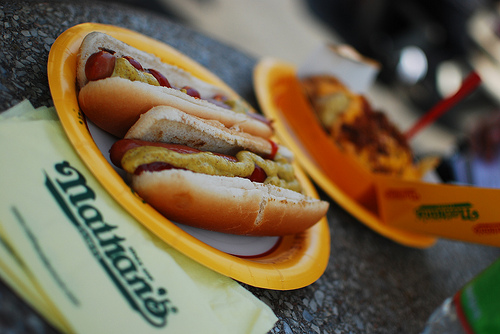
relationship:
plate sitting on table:
[41, 19, 334, 294] [5, 6, 488, 328]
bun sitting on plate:
[119, 102, 329, 239] [41, 19, 334, 294]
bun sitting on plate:
[75, 30, 276, 151] [41, 19, 334, 294]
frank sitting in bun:
[106, 135, 296, 184] [119, 102, 329, 239]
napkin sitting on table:
[4, 94, 279, 328] [5, 6, 488, 328]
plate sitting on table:
[252, 56, 437, 248] [5, 6, 488, 328]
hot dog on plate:
[108, 100, 328, 236] [41, 19, 334, 294]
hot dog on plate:
[72, 23, 275, 141] [41, 19, 334, 294]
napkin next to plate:
[4, 94, 279, 334] [41, 19, 334, 294]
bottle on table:
[419, 252, 496, 329] [5, 6, 488, 328]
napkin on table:
[4, 94, 279, 334] [5, 6, 488, 328]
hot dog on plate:
[109, 137, 304, 194] [48, 292, 329, 319]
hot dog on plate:
[83, 50, 277, 133] [48, 292, 329, 319]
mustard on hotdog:
[122, 150, 305, 189] [107, 150, 299, 190]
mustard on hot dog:
[102, 50, 165, 88] [83, 50, 277, 133]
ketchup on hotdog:
[105, 141, 304, 192] [115, 137, 303, 190]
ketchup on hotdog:
[111, 51, 204, 97] [78, 44, 276, 128]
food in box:
[294, 68, 414, 178] [270, 62, 499, 247]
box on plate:
[270, 62, 499, 247] [252, 56, 437, 248]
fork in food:
[393, 65, 485, 146] [293, 71, 444, 182]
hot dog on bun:
[109, 137, 304, 194] [119, 102, 329, 239]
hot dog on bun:
[83, 50, 277, 133] [72, 29, 278, 142]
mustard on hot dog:
[122, 150, 305, 189] [108, 156, 298, 179]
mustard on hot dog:
[109, 57, 160, 89] [83, 51, 277, 127]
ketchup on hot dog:
[262, 140, 281, 166] [108, 156, 298, 179]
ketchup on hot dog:
[115, 51, 205, 100] [83, 51, 277, 127]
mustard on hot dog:
[122, 150, 305, 189] [108, 130, 302, 187]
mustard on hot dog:
[109, 57, 160, 89] [81, 43, 276, 124]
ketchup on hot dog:
[105, 141, 304, 192] [108, 130, 302, 187]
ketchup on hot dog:
[111, 51, 204, 97] [81, 43, 276, 124]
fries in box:
[298, 70, 441, 185] [270, 62, 499, 247]